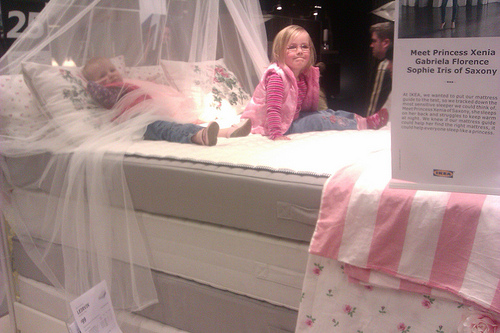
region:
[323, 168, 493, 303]
a pink and white striped blanket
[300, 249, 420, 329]
a white blanket with little pink flowers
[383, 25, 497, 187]
a white sign with black text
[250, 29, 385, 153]
a little girl sitting on a bed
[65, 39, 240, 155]
a baby girl lying back on a bed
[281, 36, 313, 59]
gold glasses on a little girl's face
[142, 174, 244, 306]
several white mattresses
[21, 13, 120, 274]
a white gauzy canopy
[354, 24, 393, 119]
the side of a man in a striped jacket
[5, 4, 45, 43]
the number 25 on a sign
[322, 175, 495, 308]
pink and white striped blanket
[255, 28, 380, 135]
little girl on bed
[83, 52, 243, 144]
little girl laying on bed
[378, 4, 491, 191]
ikea sign on bed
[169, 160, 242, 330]
mattresses stacked in pile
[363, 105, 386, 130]
red shoes on girl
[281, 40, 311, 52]
glasses on little girl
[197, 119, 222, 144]
shoe on little girl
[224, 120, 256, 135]
shoe on little girl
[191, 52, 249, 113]
floral pillow on bed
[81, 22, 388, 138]
the children on the bed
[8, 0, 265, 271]
the sheer fabric draped over the bed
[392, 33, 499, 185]
the sign on the bed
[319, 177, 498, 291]
the pink and white striped fabric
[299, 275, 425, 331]
the pink floral fabric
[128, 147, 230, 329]
the stacked matresses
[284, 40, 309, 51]
the glasses on the child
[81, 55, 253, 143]
the baby on the bed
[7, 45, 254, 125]
the pillows on the bed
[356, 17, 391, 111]
the man in the back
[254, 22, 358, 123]
child wearing pink jacket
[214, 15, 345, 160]
child wearing pink jacket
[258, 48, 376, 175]
child wearing pink jacket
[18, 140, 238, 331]
A pile of mattresses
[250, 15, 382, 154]
A little girl on a bed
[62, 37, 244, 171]
A baby on a bed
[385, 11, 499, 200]
An Ikea sign about meeting a princess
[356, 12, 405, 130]
A man in profile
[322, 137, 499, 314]
A pink striped blanket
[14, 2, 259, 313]
A canopy over a bed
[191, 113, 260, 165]
a baby's shoes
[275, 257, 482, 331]
A floral blanket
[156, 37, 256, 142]
A floral pillow on a bed